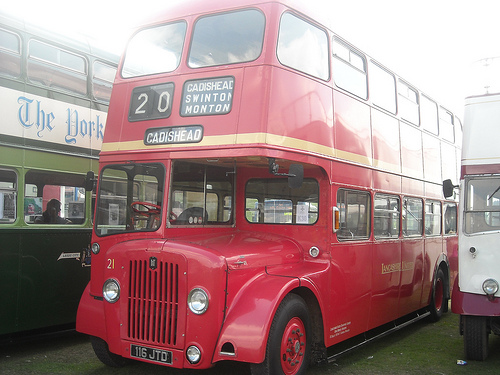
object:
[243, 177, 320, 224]
winshield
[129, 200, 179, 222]
wheel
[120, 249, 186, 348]
grill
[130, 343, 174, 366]
license plate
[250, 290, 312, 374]
wheel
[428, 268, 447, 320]
wheel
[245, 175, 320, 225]
window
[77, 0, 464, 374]
bus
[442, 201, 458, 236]
window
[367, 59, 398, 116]
window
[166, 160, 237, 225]
window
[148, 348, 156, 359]
letters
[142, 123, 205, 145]
sign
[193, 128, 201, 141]
letters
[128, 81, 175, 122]
sign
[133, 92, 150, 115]
numerals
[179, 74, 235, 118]
sign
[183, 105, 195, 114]
letters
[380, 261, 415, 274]
lettering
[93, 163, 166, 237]
window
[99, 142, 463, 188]
trim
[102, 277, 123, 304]
headlight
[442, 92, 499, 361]
bus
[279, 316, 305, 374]
rim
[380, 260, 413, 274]
writing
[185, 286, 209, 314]
headlights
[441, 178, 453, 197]
mirror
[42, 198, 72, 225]
person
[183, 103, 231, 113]
destination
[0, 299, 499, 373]
ground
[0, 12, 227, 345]
bus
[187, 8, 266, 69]
window